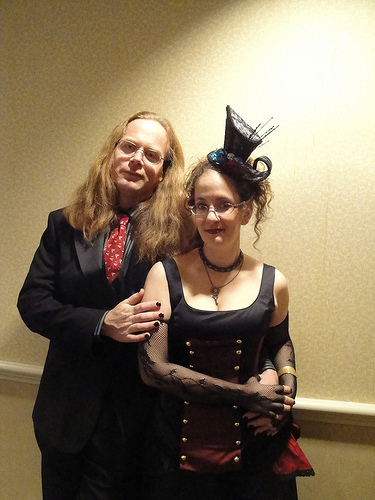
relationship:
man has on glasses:
[17, 111, 203, 498] [115, 140, 163, 165]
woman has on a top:
[137, 161, 314, 499] [160, 256, 315, 480]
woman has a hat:
[137, 161, 314, 499] [208, 108, 272, 183]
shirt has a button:
[104, 208, 152, 292] [235, 337, 243, 347]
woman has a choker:
[137, 161, 314, 499] [198, 245, 244, 273]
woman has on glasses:
[137, 161, 314, 499] [189, 199, 254, 214]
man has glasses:
[17, 111, 203, 498] [115, 140, 163, 165]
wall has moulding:
[2, 2, 372, 498] [3, 360, 373, 429]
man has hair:
[17, 111, 203, 498] [64, 110, 201, 263]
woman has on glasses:
[137, 161, 314, 499] [115, 140, 163, 165]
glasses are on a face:
[189, 199, 254, 214] [193, 170, 241, 247]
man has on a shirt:
[17, 111, 203, 498] [104, 208, 152, 292]